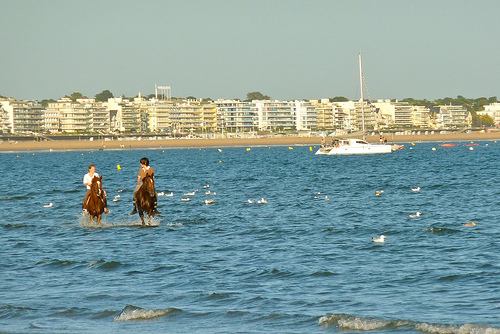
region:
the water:
[265, 182, 347, 332]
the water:
[270, 202, 312, 304]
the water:
[249, 172, 319, 314]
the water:
[289, 167, 336, 288]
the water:
[291, 250, 328, 325]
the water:
[261, 227, 318, 328]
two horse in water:
[62, 137, 211, 239]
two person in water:
[64, 154, 194, 183]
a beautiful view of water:
[11, 143, 482, 331]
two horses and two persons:
[81, 140, 191, 223]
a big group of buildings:
[14, 82, 492, 179]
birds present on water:
[279, 166, 481, 264]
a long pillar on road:
[344, 43, 384, 163]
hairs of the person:
[135, 151, 162, 166]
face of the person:
[79, 157, 109, 181]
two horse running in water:
[60, 138, 198, 263]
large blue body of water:
[8, 147, 499, 332]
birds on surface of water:
[172, 183, 485, 254]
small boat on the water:
[307, 43, 415, 158]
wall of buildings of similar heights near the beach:
[1, 93, 479, 148]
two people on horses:
[74, 148, 172, 212]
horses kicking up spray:
[67, 199, 169, 241]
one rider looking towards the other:
[70, 153, 160, 190]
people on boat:
[311, 128, 350, 157]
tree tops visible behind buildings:
[3, 86, 394, 117]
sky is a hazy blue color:
[1, 0, 493, 95]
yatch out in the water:
[313, 52, 398, 161]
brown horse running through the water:
[129, 156, 165, 230]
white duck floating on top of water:
[363, 229, 388, 246]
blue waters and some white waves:
[22, 138, 494, 319]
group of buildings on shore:
[10, 95, 475, 135]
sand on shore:
[0, 123, 497, 150]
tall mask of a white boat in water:
[355, 56, 369, 136]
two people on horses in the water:
[69, 155, 159, 224]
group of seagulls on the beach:
[85, 130, 205, 144]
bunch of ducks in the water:
[158, 175, 268, 207]